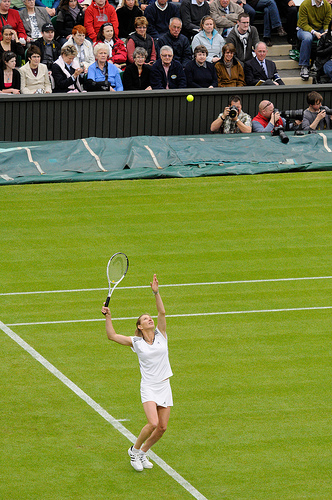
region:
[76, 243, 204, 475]
a female tennis player throwing the ball into the air to serve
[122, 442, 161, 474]
the white tennis shoes the player is wearing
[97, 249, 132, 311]
the tennis racket she is holding to hit the ball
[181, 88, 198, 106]
the green tennis ball high in the air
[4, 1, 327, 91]
a large crowd of fans watching the tennis match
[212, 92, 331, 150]
three photographers with large black cameras taking photos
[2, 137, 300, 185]
a large green tarp folded up on the side of the court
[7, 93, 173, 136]
a dark green railing before the stands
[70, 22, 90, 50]
a woman watching with bright red hair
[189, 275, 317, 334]
two white lines drawn on the court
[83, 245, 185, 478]
Tennis player getting ready to hit ball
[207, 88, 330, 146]
People [hotographing the tennis action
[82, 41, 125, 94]
Older woman with her arm in a sling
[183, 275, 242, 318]
White lines showing out of bounds area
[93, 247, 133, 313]
Tennis racquet used for hitting tennis ball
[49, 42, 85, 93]
Woman wearing a scarf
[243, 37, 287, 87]
Man dressed in suit and tie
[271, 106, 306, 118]
Camera with telephoto lens for distant shots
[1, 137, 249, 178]
Tarp used to cover tennis court during bad weather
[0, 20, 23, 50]
Woman with her hand on her forehead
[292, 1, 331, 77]
a person wearing a green sweater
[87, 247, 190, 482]
a tennis player waiting for the ball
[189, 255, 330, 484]
the green grass of a tennis field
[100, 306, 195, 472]
a woman wearing all white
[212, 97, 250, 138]
a man holding a camera to his eye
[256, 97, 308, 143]
a man with sunglasses perked on his head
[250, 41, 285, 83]
a man with grey hair wearing a suit and tie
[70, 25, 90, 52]
a woman with red hair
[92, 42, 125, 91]
a woman with white hair wearing a blue shirt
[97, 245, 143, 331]
a black and white tennis racket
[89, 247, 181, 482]
lady playing tennis on a grass court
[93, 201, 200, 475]
lady wearing white tennis shoes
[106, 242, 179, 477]
lady wearing white ankle socks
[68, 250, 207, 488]
lady wearing white tennis skirt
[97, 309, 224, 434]
lady wearing white pullover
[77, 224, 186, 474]
lady using a metal racquet with a black handle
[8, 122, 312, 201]
green tarp on the back of the tennis court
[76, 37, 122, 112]
woman wearing blue jacket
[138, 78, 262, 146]
yellow tennis ball in the air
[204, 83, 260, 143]
man taking pictures of a tennis player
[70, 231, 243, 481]
woman in tennis clothing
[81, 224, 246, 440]
woman with tennis racket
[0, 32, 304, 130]
audience watching a tennis match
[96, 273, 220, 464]
woman wearing tennis skirt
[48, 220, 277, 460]
woman in all white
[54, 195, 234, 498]
woman about to hit a tennis ball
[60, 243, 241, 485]
woman playing in a tennis game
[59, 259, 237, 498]
woman with legs bent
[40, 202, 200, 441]
woman looking up at the sky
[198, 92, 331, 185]
photographers taking photos